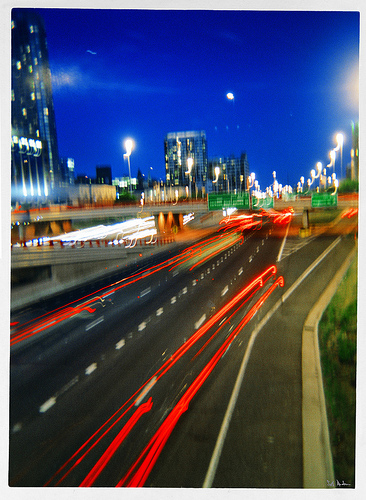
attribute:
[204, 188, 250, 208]
street sign — white, green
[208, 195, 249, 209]
sign — green, white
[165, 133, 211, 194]
building — has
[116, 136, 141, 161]
light — in the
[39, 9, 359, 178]
sky — has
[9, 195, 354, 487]
highway — has a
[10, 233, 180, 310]
ramp — to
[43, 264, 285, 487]
streaks — bright, red, neon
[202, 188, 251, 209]
sign — over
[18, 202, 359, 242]
bridge — has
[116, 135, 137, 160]
light — in the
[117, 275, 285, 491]
light — from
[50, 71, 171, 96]
clouds — white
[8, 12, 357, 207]
sky — blue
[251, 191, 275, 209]
sign — white, green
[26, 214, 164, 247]
lights — neon, bright, white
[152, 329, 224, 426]
breaklights — from 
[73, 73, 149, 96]
clouds — white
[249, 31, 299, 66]
sky — blue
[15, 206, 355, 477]
cars — very fast, moving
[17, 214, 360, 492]
highway — is a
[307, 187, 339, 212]
sign — green, white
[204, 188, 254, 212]
sign — white, green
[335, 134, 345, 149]
light — bright, white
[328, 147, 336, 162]
light — bright, white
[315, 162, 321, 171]
light — bright, white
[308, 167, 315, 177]
light — bright, white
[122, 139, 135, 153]
light — bright, white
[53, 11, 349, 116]
sky — blue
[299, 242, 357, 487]
curb — concrete, curved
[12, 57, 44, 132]
windows — on a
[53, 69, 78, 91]
clouds — in the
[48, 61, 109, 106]
clouds — white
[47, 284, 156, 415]
lines — white, dashed